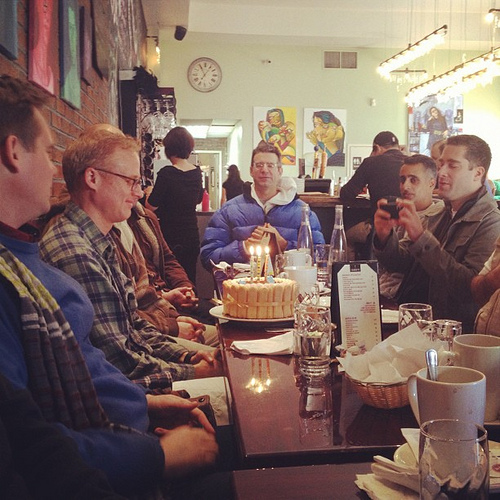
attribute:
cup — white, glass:
[297, 309, 335, 369]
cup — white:
[415, 365, 488, 445]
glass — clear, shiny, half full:
[306, 306, 332, 370]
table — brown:
[208, 264, 498, 457]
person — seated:
[419, 139, 493, 330]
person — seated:
[380, 158, 432, 268]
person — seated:
[233, 149, 317, 260]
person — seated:
[126, 200, 205, 328]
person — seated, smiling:
[69, 126, 172, 370]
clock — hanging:
[184, 53, 225, 100]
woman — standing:
[168, 129, 211, 270]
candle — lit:
[266, 243, 274, 286]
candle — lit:
[255, 243, 266, 289]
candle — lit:
[241, 245, 256, 284]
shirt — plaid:
[51, 211, 172, 382]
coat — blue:
[217, 184, 321, 252]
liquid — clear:
[299, 333, 332, 372]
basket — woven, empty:
[357, 356, 414, 408]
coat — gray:
[438, 211, 496, 309]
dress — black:
[151, 167, 208, 267]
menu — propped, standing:
[329, 260, 385, 351]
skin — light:
[99, 161, 135, 227]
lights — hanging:
[372, 23, 467, 77]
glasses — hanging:
[144, 93, 175, 132]